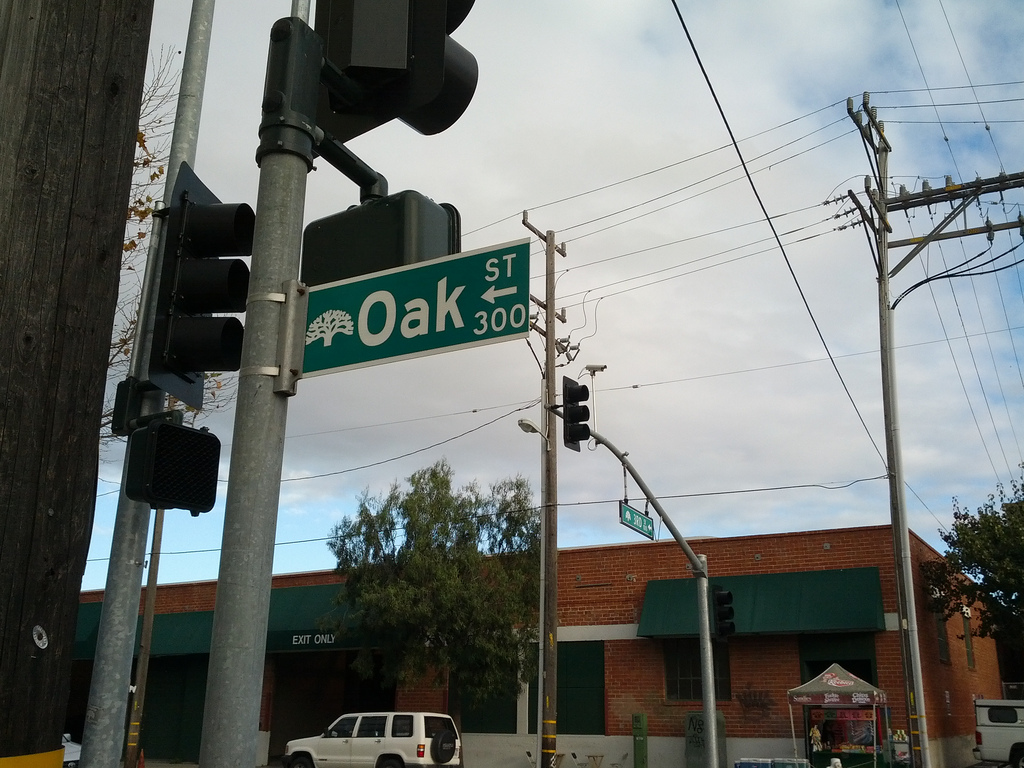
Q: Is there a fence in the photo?
A: No, there are no fences.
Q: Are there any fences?
A: No, there are no fences.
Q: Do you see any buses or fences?
A: No, there are no fences or buses.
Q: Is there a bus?
A: No, there are no buses.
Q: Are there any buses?
A: No, there are no buses.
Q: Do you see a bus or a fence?
A: No, there are no buses or fences.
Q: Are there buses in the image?
A: No, there are no buses.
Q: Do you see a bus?
A: No, there are no buses.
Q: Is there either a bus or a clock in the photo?
A: No, there are no buses or clocks.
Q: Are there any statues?
A: No, there are no statues.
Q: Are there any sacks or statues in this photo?
A: No, there are no statues or sacks.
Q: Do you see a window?
A: Yes, there is a window.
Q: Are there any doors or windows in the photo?
A: Yes, there is a window.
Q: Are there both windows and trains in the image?
A: No, there is a window but no trains.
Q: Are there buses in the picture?
A: No, there are no buses.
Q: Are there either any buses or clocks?
A: No, there are no buses or clocks.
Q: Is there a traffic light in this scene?
A: Yes, there is a traffic light.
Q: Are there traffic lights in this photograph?
A: Yes, there is a traffic light.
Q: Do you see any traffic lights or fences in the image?
A: Yes, there is a traffic light.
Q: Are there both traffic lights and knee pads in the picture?
A: No, there is a traffic light but no knee pads.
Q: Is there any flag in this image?
A: No, there are no flags.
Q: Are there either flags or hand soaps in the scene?
A: No, there are no flags or hand soaps.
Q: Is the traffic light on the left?
A: Yes, the traffic light is on the left of the image.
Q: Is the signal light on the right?
A: No, the signal light is on the left of the image.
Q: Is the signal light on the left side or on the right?
A: The signal light is on the left of the image.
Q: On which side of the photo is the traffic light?
A: The traffic light is on the left of the image.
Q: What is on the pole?
A: The traffic light is on the pole.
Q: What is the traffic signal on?
A: The traffic signal is on the pole.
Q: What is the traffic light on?
A: The traffic signal is on the pole.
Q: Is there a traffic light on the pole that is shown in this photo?
A: Yes, there is a traffic light on the pole.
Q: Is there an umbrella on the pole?
A: No, there is a traffic light on the pole.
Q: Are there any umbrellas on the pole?
A: No, there is a traffic light on the pole.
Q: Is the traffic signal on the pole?
A: Yes, the traffic signal is on the pole.